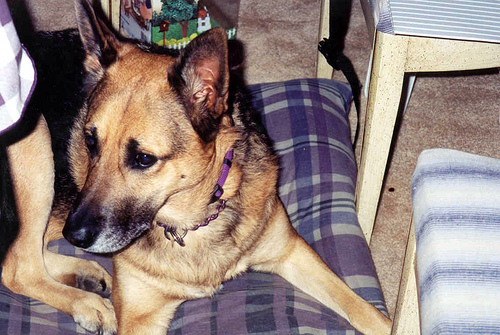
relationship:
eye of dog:
[131, 149, 156, 169] [0, 10, 325, 322]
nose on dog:
[59, 220, 96, 247] [0, 0, 386, 334]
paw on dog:
[73, 293, 118, 333] [0, 0, 386, 334]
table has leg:
[354, 1, 498, 249] [347, 17, 405, 249]